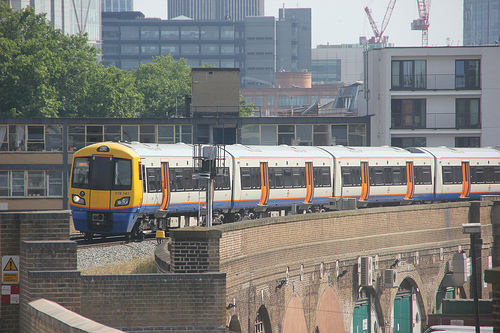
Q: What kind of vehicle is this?
A: Train.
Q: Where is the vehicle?
A: Train tracks.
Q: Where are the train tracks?
A: Raised brick platform.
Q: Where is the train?
A: City.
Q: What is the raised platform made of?
A: Brick.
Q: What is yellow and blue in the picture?
A: A train.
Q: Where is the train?
A: On the bridge.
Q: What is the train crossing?
A: The bridge.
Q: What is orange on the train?
A: Doors.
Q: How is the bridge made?
A: Of brick.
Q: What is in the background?
A: Buildings.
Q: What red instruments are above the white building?
A: Cranes.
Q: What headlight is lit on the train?
A: The left one.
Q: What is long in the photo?
A: The train.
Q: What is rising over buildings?
A: Green treetops.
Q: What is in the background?
A: Tall buildings.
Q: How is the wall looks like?
A: Brick wall.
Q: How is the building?
A: Tall.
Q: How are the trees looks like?
A: Green.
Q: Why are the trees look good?
A: Leafy.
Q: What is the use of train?
A: Travel.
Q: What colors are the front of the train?
A: Yellow and blue.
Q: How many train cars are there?
A: 4.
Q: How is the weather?
A: Sunny.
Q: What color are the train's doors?
A: Orange.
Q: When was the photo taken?
A: Daytime.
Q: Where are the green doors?
A: Below train.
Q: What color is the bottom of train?
A: Blue.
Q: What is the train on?
A: Train track.